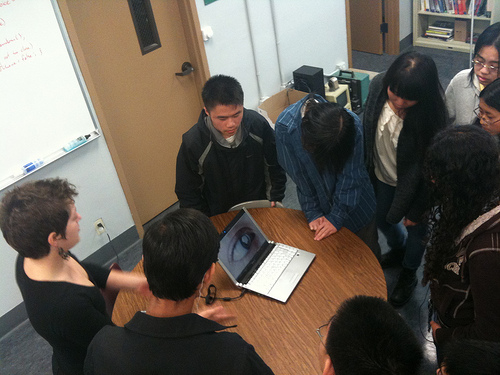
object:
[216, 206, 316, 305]
laptop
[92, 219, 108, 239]
outlet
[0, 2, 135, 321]
wall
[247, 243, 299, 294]
track pad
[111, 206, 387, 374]
table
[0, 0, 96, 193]
white board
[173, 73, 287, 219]
man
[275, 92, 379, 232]
shirt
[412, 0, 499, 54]
book case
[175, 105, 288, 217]
jacket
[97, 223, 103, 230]
plug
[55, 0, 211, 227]
door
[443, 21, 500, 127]
kid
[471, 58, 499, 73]
glasses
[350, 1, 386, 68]
door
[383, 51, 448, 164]
hair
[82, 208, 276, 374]
man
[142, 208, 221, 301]
head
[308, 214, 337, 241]
hands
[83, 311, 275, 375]
shirt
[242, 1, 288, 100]
molding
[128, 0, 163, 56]
window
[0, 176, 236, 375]
person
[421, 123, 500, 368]
person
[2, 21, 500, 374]
people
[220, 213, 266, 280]
screen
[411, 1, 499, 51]
shelf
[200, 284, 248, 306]
cord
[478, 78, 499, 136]
woman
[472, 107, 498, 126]
eyeglasses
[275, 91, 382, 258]
boy